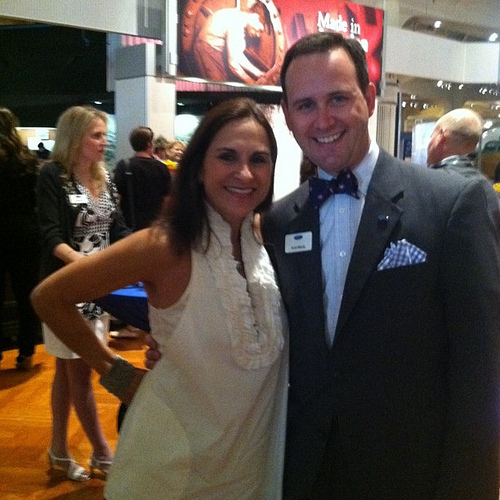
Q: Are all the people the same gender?
A: No, they are both male and female.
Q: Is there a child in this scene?
A: No, there are no children.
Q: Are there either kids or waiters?
A: No, there are no kids or waiters.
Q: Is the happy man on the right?
A: Yes, the man is on the right of the image.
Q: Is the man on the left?
A: No, the man is on the right of the image.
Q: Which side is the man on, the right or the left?
A: The man is on the right of the image.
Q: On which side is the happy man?
A: The man is on the right of the image.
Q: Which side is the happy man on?
A: The man is on the right of the image.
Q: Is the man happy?
A: Yes, the man is happy.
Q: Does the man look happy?
A: Yes, the man is happy.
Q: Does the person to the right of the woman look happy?
A: Yes, the man is happy.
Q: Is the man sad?
A: No, the man is happy.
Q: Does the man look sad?
A: No, the man is happy.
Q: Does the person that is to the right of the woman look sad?
A: No, the man is happy.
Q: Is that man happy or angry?
A: The man is happy.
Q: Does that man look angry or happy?
A: The man is happy.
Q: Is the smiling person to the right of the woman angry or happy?
A: The man is happy.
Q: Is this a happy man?
A: Yes, this is a happy man.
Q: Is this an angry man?
A: No, this is a happy man.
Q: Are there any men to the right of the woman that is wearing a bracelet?
A: Yes, there is a man to the right of the woman.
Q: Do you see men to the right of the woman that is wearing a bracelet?
A: Yes, there is a man to the right of the woman.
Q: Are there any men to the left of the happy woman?
A: No, the man is to the right of the woman.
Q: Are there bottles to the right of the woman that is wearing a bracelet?
A: No, there is a man to the right of the woman.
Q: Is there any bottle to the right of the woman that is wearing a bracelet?
A: No, there is a man to the right of the woman.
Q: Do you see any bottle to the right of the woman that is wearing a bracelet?
A: No, there is a man to the right of the woman.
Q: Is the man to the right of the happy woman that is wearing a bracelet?
A: Yes, the man is to the right of the woman.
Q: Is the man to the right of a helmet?
A: No, the man is to the right of the woman.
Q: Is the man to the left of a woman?
A: No, the man is to the right of a woman.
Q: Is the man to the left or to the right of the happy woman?
A: The man is to the right of the woman.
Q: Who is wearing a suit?
A: The man is wearing a suit.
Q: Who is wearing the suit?
A: The man is wearing a suit.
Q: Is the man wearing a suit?
A: Yes, the man is wearing a suit.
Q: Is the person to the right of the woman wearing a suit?
A: Yes, the man is wearing a suit.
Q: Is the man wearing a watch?
A: No, the man is wearing a suit.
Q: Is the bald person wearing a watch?
A: No, the man is wearing a suit.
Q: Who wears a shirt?
A: The man wears a shirt.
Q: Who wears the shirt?
A: The man wears a shirt.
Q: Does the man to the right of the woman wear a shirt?
A: Yes, the man wears a shirt.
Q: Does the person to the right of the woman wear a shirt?
A: Yes, the man wears a shirt.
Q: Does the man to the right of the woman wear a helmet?
A: No, the man wears a shirt.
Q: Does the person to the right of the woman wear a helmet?
A: No, the man wears a shirt.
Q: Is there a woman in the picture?
A: Yes, there is a woman.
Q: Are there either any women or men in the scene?
A: Yes, there is a woman.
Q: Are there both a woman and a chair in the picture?
A: No, there is a woman but no chairs.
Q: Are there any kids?
A: No, there are no kids.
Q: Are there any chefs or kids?
A: No, there are no kids or chefs.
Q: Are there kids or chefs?
A: No, there are no kids or chefs.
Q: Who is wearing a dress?
A: The woman is wearing a dress.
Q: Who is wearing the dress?
A: The woman is wearing a dress.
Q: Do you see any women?
A: Yes, there is a woman.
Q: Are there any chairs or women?
A: Yes, there is a woman.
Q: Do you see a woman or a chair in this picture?
A: Yes, there is a woman.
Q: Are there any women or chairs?
A: Yes, there is a woman.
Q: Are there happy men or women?
A: Yes, there is a happy woman.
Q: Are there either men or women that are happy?
A: Yes, the woman is happy.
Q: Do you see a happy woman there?
A: Yes, there is a happy woman.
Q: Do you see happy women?
A: Yes, there is a happy woman.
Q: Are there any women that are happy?
A: Yes, there is a woman that is happy.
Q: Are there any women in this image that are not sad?
A: Yes, there is a happy woman.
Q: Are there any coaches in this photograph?
A: No, there are no coaches.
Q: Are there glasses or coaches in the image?
A: No, there are no coaches or glasses.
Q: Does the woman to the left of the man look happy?
A: Yes, the woman is happy.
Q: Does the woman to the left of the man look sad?
A: No, the woman is happy.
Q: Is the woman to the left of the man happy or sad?
A: The woman is happy.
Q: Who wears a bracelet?
A: The woman wears a bracelet.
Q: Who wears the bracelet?
A: The woman wears a bracelet.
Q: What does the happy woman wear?
A: The woman wears a bracelet.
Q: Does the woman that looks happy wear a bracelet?
A: Yes, the woman wears a bracelet.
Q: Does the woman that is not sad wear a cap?
A: No, the woman wears a bracelet.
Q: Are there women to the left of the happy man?
A: Yes, there is a woman to the left of the man.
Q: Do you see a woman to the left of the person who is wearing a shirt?
A: Yes, there is a woman to the left of the man.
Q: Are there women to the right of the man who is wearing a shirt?
A: No, the woman is to the left of the man.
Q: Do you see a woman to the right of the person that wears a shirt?
A: No, the woman is to the left of the man.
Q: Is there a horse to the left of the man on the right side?
A: No, there is a woman to the left of the man.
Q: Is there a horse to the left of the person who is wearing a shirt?
A: No, there is a woman to the left of the man.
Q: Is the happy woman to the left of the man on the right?
A: Yes, the woman is to the left of the man.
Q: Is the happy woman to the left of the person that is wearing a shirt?
A: Yes, the woman is to the left of the man.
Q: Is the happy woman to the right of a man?
A: No, the woman is to the left of a man.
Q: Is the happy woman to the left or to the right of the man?
A: The woman is to the left of the man.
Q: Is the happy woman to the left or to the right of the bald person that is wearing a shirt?
A: The woman is to the left of the man.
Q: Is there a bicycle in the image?
A: No, there are no bicycles.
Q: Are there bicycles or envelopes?
A: No, there are no bicycles or envelopes.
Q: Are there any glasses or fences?
A: No, there are no glasses or fences.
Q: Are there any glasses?
A: No, there are no glasses.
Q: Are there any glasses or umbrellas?
A: No, there are no glasses or umbrellas.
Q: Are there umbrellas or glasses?
A: No, there are no glasses or umbrellas.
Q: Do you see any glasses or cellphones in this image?
A: No, there are no glasses or cellphones.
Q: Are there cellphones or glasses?
A: No, there are no glasses or cellphones.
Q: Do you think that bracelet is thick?
A: Yes, the bracelet is thick.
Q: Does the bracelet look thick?
A: Yes, the bracelet is thick.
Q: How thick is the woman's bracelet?
A: The bracelet is thick.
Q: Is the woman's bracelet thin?
A: No, the bracelet is thick.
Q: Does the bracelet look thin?
A: No, the bracelet is thick.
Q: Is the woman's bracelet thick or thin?
A: The bracelet is thick.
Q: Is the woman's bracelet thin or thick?
A: The bracelet is thick.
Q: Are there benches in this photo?
A: No, there are no benches.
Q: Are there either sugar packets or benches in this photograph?
A: No, there are no benches or sugar packets.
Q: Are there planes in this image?
A: No, there are no planes.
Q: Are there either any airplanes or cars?
A: No, there are no airplanes or cars.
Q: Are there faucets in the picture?
A: No, there are no faucets.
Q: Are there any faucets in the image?
A: No, there are no faucets.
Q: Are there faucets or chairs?
A: No, there are no faucets or chairs.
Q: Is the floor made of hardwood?
A: Yes, the floor is made of hardwood.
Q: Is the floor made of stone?
A: No, the floor is made of hardwood.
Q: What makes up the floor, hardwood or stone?
A: The floor is made of hardwood.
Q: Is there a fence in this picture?
A: No, there are no fences.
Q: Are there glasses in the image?
A: No, there are no glasses.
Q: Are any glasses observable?
A: No, there are no glasses.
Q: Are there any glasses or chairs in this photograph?
A: No, there are no glasses or chairs.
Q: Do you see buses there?
A: No, there are no buses.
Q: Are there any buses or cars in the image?
A: No, there are no buses or cars.